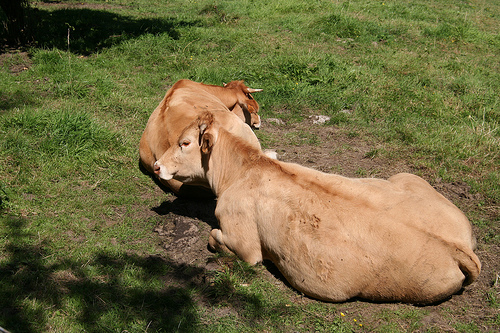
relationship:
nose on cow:
[149, 153, 178, 187] [152, 110, 437, 306]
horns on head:
[219, 71, 271, 96] [145, 113, 221, 183]